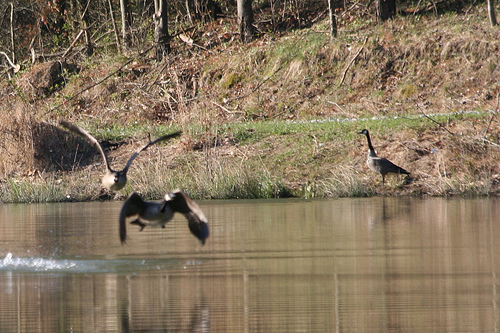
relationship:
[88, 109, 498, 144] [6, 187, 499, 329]
grass on side of pond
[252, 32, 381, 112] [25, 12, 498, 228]
tree limbs on hill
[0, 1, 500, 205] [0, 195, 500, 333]
grass on embarkments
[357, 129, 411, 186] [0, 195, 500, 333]
bird on embarkments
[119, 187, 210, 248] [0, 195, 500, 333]
bird on embarkments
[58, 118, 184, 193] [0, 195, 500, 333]
bird on embarkments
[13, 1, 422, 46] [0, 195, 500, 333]
trees near embarkments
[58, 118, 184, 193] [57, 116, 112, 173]
bird has extended bird wings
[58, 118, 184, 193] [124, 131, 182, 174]
bird has extended bird wings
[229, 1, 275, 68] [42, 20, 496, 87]
trunk on tree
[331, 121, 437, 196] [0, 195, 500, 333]
bird beside embarkments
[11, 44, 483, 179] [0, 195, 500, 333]
embankment beside embarkments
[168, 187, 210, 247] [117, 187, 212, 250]
bird wings on bird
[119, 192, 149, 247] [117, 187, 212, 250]
bird wings on bird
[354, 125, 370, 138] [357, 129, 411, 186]
face on bird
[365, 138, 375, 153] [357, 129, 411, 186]
neck on bird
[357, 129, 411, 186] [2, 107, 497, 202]
bird on embankment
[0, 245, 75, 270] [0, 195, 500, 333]
splash mark on embarkments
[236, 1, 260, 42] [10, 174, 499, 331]
trunk on embarkments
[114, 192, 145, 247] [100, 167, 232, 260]
bird wings on bird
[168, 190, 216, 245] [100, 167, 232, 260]
bird wings on bird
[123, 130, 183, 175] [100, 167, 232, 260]
bird wings on bird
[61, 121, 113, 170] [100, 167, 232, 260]
bird wings on bird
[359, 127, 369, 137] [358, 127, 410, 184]
head on bird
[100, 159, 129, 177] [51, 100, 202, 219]
head on bird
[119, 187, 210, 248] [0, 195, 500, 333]
bird are around embarkments